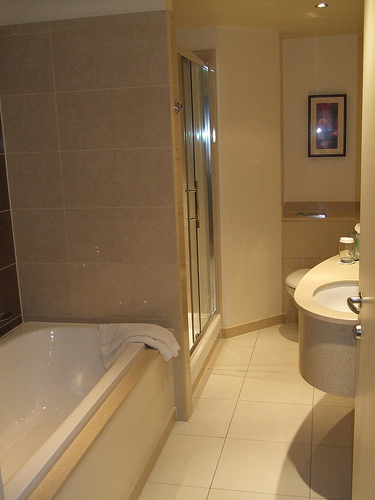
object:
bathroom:
[0, 1, 364, 500]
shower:
[177, 52, 220, 359]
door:
[179, 57, 217, 353]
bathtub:
[1, 320, 176, 499]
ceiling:
[174, 2, 364, 38]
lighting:
[317, 2, 328, 11]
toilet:
[285, 269, 313, 343]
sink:
[312, 280, 358, 314]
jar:
[339, 238, 357, 264]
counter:
[295, 249, 360, 329]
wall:
[0, 0, 186, 420]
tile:
[0, 10, 187, 421]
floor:
[139, 324, 356, 500]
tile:
[139, 320, 354, 499]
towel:
[96, 324, 180, 373]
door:
[350, 2, 373, 500]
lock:
[352, 325, 362, 339]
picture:
[308, 94, 346, 157]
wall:
[282, 33, 364, 323]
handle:
[188, 179, 201, 231]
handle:
[346, 294, 363, 314]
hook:
[174, 100, 186, 112]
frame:
[310, 95, 348, 157]